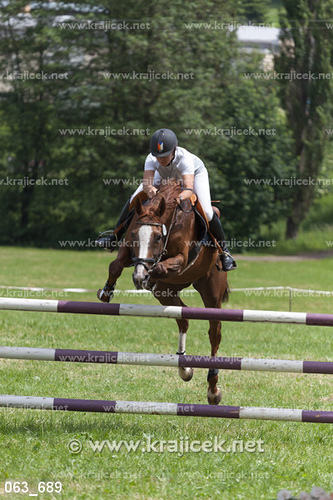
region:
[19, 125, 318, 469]
Picture of horse jumping an obstacle.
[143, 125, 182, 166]
A black safety helmet.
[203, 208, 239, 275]
Riding boot on left leg.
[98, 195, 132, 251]
Riding boot on right leg.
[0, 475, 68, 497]
The numbers 063_689 in white letters.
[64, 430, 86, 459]
A white copyright symbol.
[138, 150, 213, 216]
A white riding outfit.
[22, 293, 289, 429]
Three poles making up an obstacle.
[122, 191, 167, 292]
A horse's head with white stripe.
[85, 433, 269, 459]
Website address www.krajicek.net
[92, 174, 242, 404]
a horse clearing a hurdle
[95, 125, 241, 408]
a horse and rider doing a trick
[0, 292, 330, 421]
purple and white hurdle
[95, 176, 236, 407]
a horse jumping very high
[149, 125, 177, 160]
a black horseback riding helmet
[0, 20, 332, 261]
very leafy trees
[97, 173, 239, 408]
a brown and white horse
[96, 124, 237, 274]
a horseback rider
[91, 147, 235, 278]
the uniform of a horseback rider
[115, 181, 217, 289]
a saddle and bridle on a horse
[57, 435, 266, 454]
A repeated krajicek.net watermark.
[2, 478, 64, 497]
A camera's ID number for an image.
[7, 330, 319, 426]
A man-made equestrian jump.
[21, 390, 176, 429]
A purple-and-white beam.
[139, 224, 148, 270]
A white stripe down a brown horse's nose.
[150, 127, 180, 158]
A black riding helmet.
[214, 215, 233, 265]
A black riding boot.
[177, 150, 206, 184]
A short-sleeve white shirt.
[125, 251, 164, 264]
A horse's black bridle around its face.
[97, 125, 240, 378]
A horse leaping over a trio of beams.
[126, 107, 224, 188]
Black helmet on rider's head.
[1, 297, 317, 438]
Hurdle in front of horse.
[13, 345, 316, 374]
White and black hurdle.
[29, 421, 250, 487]
Grass under hurdle.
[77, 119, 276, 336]
Horse jumping in the air.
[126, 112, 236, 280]
Rider on the back of a horse.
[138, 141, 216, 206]
Horse rider with white shirt.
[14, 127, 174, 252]
Trees in the background.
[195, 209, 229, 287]
Black riding boots on the rider.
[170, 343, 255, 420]
Hooves on the jumping horse.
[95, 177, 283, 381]
Brown jumping horse.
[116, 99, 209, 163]
Black helmet on man's head.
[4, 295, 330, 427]
Black and white hurdle.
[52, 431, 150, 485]
Green grass under hurdle.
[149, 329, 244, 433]
Hooves on horse.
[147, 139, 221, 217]
White outfit on horse rider.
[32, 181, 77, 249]
Trees behind the grass.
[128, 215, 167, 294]
White stripe on horse's face.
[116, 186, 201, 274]
Reins on horse.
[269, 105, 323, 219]
Brown trunk of the tree.